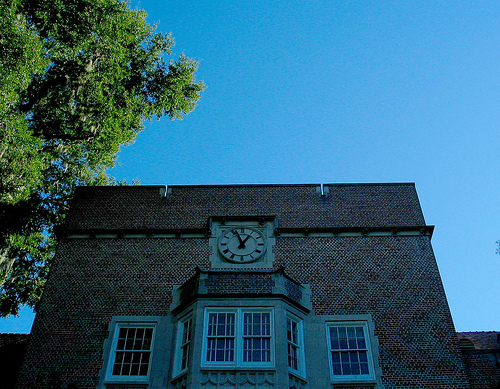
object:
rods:
[205, 335, 235, 339]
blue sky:
[1, 0, 500, 338]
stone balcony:
[170, 265, 312, 317]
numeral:
[255, 236, 262, 240]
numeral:
[255, 249, 262, 254]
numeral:
[229, 253, 235, 260]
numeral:
[220, 242, 227, 246]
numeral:
[223, 235, 229, 239]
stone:
[386, 265, 407, 287]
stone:
[317, 247, 342, 273]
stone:
[201, 371, 274, 387]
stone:
[395, 318, 422, 346]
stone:
[113, 282, 136, 304]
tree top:
[2, 0, 204, 315]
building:
[1, 182, 500, 389]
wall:
[12, 181, 474, 389]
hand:
[237, 229, 256, 250]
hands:
[234, 228, 247, 250]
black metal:
[231, 229, 238, 234]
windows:
[284, 311, 308, 378]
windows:
[178, 309, 197, 376]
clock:
[210, 215, 275, 268]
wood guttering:
[51, 214, 438, 241]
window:
[108, 319, 156, 380]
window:
[199, 304, 274, 369]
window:
[323, 317, 373, 383]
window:
[205, 310, 237, 366]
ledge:
[171, 366, 312, 388]